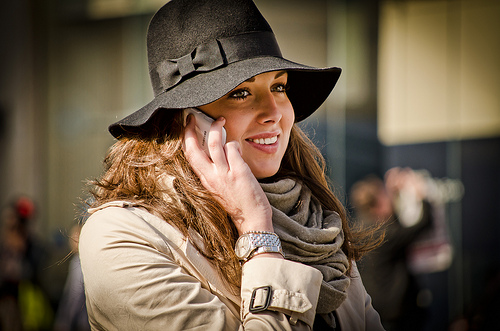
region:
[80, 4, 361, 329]
this is a lady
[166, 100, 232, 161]
she is speaking through the phone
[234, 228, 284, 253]
this is the wrist watch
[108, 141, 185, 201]
this is the hair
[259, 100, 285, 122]
this is the nose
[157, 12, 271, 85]
she is wearing a hat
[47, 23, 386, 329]
the lady is beautiful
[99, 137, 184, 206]
the hair is long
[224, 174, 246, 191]
the lady is light skinned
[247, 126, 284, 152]
the lady is smiling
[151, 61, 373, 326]
a lady is talking on the phone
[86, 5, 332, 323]
a lady is on phone smilling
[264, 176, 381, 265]
the scarf is gray in color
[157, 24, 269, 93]
the cape is black in color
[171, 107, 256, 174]
th phone is white in color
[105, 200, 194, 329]
th jacket is gray in color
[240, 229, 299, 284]
the lay has two watches on one hand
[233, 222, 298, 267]
watch is silvery in color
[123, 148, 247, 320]
the hair is long and unkempt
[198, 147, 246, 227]
the lady is lightskinned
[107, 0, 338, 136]
The woman is wearing a black hat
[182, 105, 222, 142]
The cell phone is white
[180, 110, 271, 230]
A cell phone in the woman's right hand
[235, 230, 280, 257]
The woman is wearing a watch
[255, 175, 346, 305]
The woman is wearing a scarf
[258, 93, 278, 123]
The nose of the woman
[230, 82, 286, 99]
The eyes of the woman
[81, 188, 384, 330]
The woman is wearing a brown coat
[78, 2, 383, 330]
A woman on her cell phone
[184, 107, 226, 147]
The cell phone is rectangular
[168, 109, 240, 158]
phone to the ear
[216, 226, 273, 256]
watch on right wrist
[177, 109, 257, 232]
right hand holding the phone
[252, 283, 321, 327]
buckle on the jacket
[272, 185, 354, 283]
scarf around the neck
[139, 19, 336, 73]
black hat on girl's head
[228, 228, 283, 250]
watch is silver and gold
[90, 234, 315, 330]
coat is light tan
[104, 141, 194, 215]
girls hair is light brown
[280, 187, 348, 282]
scarf is gray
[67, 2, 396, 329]
a woman on phone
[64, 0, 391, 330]
a beautiful woman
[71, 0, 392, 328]
a woman wearing hat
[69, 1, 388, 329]
a woman wearing a scarf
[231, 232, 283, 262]
a watch the woman is wearing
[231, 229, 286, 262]
a watch on wrist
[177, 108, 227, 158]
phone the woman is using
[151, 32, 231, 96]
bow on the hat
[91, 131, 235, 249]
a brown hair of the woman